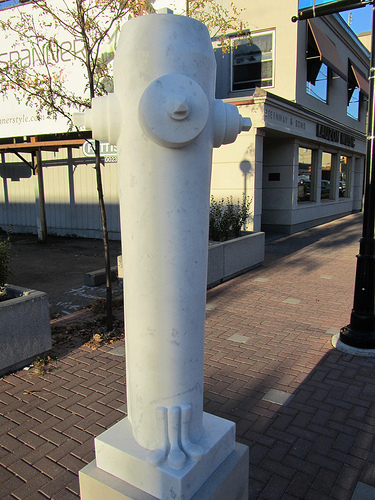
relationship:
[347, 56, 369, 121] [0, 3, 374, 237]
window on building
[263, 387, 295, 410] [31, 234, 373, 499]
brick on sidewalk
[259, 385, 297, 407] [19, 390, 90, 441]
brick on sidewalk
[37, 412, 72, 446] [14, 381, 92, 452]
brick on sidewalk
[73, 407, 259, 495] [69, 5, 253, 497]
base on concrete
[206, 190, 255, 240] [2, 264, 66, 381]
plants growing in planter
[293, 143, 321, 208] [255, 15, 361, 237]
window on building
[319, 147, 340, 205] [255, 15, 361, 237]
window on building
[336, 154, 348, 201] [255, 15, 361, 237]
window on building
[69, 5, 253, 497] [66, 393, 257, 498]
concrete on base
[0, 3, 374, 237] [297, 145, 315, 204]
building has window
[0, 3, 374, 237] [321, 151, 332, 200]
building has window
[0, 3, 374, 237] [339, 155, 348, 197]
building has window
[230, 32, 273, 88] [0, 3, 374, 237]
window on side of building